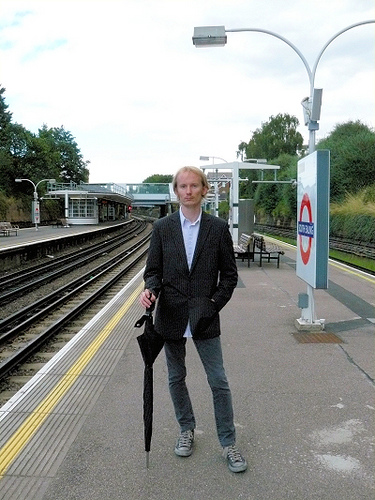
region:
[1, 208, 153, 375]
Railway tracks on the ground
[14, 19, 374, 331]
Lights on the poles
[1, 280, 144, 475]
Yellow line on the platforms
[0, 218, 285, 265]
Benches on the platforms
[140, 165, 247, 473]
Man standing on the platform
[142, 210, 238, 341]
Coat on the man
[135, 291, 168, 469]
Umbrella in the man's hand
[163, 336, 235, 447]
Jeans on the man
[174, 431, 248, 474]
Shoes on the man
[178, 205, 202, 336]
White shirt on the man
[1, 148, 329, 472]
a man waiting at a public transportation station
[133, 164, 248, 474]
a man holding an umbrella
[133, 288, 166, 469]
a black umbrella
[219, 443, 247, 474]
a Converse Chuck Taylor sneaker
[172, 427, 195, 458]
a Converse Chuck Taylor sneaker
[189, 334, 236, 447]
a leg wearing blue jeans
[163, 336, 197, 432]
a leg wearing blue jeans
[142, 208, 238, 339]
a black jacket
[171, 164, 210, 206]
head of a man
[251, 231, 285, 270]
a bench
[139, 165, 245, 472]
the man at the station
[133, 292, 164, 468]
the umbrella in the man's hand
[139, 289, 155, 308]
the man's hand holding the umbrella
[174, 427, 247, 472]
the shoes on the man's feet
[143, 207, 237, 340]
the jacket on the man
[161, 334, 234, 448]
the pants on the man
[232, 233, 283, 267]
the benches behind the man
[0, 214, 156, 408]
the train tracks on the ground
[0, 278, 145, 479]
the yellow line on the ground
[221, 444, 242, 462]
the lace on the man's shoe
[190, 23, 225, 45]
an overhead platform light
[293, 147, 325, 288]
a platform advertisement sign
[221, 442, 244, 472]
a grey and white tennis shoe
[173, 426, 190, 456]
a grey and white tennis shoe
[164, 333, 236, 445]
a pair of blue jeans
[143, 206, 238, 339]
a man's black coat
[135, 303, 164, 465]
a long black umbrella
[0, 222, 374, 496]
a train boarding platform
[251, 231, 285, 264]
a wooden park bench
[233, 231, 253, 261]
a wooden park bench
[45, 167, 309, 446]
this is a public transit stop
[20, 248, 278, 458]
this is a train station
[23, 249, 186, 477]
this is a platform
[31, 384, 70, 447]
the line is yellow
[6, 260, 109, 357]
these are train tracks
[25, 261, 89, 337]
there are two sets of tracks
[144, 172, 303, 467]
this is a man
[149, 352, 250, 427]
the man is wearing light blue jeans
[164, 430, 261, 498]
the man is wearing gray shoes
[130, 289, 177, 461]
the man is holding an umbrella